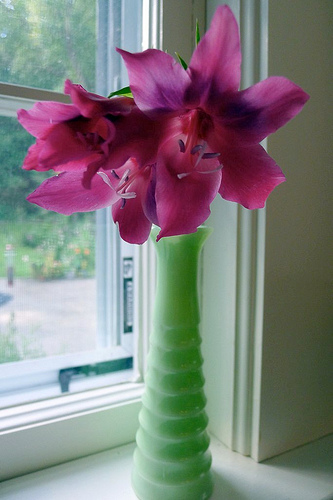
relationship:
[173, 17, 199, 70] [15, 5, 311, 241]
leaves are behind flowers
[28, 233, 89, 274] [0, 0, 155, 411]
flowers visible outside window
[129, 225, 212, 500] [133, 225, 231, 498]
glass made of glass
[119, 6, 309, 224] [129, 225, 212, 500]
flower in glass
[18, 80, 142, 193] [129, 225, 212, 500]
flower in glass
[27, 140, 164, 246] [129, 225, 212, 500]
flower in glass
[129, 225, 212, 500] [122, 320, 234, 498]
glass has ridges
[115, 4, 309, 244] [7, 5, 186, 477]
flower next to window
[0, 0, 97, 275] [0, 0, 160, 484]
tree outside window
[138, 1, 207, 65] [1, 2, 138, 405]
white trim of window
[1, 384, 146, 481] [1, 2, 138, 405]
white trim of window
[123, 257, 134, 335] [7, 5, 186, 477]
sticker on window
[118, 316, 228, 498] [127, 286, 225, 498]
ripples on vase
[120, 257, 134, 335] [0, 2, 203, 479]
sticker on window